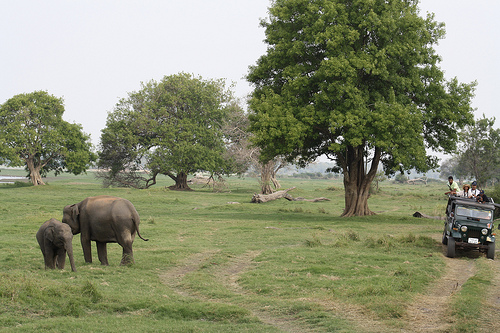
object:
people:
[476, 190, 489, 203]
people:
[459, 185, 473, 198]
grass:
[0, 322, 37, 333]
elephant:
[35, 218, 78, 272]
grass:
[0, 188, 12, 198]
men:
[444, 175, 463, 197]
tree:
[95, 69, 254, 187]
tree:
[1, 90, 96, 186]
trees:
[245, 0, 469, 221]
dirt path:
[277, 316, 295, 329]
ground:
[15, 269, 476, 331]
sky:
[1, 0, 498, 87]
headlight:
[482, 228, 489, 235]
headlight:
[461, 226, 468, 233]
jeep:
[440, 196, 500, 259]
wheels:
[442, 236, 456, 257]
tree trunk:
[249, 187, 294, 206]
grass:
[196, 192, 217, 202]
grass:
[16, 257, 32, 269]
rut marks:
[417, 321, 445, 330]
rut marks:
[190, 251, 209, 262]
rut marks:
[166, 283, 195, 291]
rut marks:
[271, 319, 300, 328]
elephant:
[62, 194, 149, 267]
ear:
[67, 203, 79, 219]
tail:
[131, 219, 148, 243]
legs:
[80, 240, 93, 264]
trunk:
[261, 175, 273, 194]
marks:
[247, 246, 261, 253]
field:
[182, 219, 412, 261]